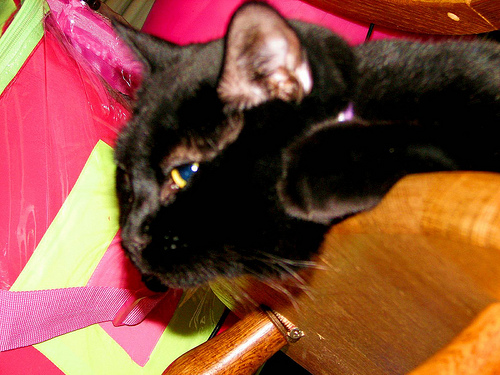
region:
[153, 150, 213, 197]
The eye is yellow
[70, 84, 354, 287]
Dark cat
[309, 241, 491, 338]
The chair is wooden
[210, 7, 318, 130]
The ear is pink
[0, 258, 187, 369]
Pink strap near the cat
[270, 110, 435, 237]
Cats paw is dark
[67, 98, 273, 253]
The cat is awake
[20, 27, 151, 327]
Colorful pattern near the kitty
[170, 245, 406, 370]
The cat has many wiskers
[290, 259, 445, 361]
Brown chair under the cat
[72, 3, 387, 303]
head of a cat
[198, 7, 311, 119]
ear of a cat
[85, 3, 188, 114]
ear of a cat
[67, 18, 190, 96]
an ear of a cat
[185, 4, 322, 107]
an ear of a cat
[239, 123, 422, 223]
paw of a cat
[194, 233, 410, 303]
whisker of a cat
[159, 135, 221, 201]
eye of a cat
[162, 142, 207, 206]
an eye of a cat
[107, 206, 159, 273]
nose of a cat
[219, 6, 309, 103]
Inside of the cat's ear.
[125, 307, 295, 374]
Brown wooden leg of a chair.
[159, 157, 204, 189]
Light reflection in the cat's eye.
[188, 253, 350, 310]
White cat whiskers.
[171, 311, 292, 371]
Light reflection on the stool's leg.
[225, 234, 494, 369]
Bottom of the chair.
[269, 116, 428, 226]
Cat's front paw.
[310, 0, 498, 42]
The bottom of a wooden table.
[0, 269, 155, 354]
Pink strap of the cat's leash.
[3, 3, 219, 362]
A pink and green package.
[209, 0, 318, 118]
ear of a black cat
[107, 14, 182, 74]
ear of a black cat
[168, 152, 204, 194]
eye of a black cat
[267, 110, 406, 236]
paw of a black cat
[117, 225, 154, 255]
nose of a black cat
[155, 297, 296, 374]
wooden table leg under the cat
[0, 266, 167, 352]
pink strap with a pink buckle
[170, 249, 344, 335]
white whiskers of a cat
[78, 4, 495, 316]
black cat laying on a chair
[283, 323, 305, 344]
screw on the bottom of a chair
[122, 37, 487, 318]
the kitten is black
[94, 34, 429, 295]
the kitten is sleepy